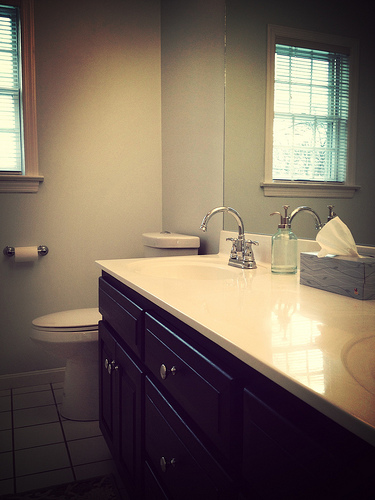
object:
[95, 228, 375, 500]
vanity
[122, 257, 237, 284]
sink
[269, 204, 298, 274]
dispenser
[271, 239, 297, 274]
soap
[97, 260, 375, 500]
cabinet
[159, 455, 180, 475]
knobs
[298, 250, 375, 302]
box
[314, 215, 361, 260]
tissue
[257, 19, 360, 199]
reflection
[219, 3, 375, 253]
mirror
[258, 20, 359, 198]
window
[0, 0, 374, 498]
bathroom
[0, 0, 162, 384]
wall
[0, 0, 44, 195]
window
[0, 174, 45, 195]
sill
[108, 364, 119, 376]
hardware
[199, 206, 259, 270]
faucet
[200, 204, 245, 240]
curve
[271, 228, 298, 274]
glass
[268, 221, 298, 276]
bottle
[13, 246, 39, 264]
toilet paper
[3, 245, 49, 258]
holder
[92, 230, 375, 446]
counter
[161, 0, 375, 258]
wall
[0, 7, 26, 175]
mini blinds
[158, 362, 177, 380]
hardware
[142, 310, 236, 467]
drawer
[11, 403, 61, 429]
tile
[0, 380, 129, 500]
floor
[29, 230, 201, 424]
toilet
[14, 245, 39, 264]
roll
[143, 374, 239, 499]
drawer pulls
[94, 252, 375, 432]
counter top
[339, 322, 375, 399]
sinks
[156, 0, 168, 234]
corner